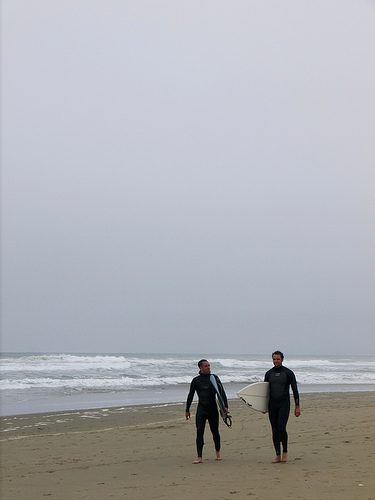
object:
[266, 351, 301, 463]
man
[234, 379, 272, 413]
board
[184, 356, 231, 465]
man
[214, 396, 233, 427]
board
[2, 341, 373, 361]
horizon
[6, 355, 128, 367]
wave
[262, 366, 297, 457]
wetsuit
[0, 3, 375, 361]
sky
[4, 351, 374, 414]
ocean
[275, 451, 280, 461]
feet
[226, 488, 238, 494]
footprints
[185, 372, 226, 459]
wetsuit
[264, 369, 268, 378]
arm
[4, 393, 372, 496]
sand